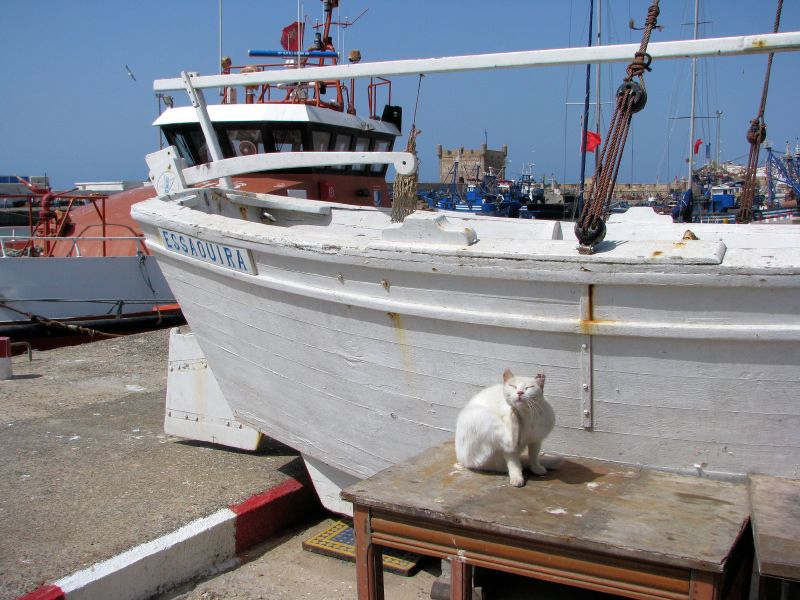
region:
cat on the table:
[444, 378, 542, 495]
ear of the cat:
[491, 366, 519, 377]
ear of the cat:
[532, 376, 552, 388]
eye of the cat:
[499, 379, 521, 388]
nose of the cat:
[512, 386, 525, 399]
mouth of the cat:
[502, 395, 531, 407]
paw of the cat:
[504, 464, 526, 491]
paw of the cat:
[523, 462, 551, 478]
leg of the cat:
[453, 446, 497, 479]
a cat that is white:
[429, 367, 589, 488]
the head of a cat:
[493, 369, 554, 410]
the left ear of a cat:
[521, 369, 557, 391]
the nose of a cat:
[514, 390, 527, 406]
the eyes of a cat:
[507, 378, 536, 391]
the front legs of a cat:
[484, 408, 552, 481]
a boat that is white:
[118, 166, 796, 502]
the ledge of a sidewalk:
[61, 518, 294, 575]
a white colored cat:
[445, 362, 568, 485]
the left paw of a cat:
[475, 442, 527, 494]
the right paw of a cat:
[521, 442, 553, 480]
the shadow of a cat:
[560, 438, 614, 506]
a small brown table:
[347, 454, 671, 598]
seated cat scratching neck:
[452, 369, 553, 486]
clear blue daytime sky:
[3, 1, 796, 188]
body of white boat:
[132, 192, 796, 552]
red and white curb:
[30, 481, 315, 598]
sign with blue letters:
[159, 227, 253, 279]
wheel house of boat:
[163, 100, 403, 199]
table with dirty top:
[344, 440, 746, 596]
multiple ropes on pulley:
[573, 2, 664, 250]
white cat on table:
[442, 357, 567, 487]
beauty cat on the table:
[476, 389, 554, 462]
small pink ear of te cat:
[496, 363, 517, 384]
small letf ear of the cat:
[533, 373, 545, 391]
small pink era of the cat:
[534, 377, 548, 387]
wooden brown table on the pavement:
[364, 489, 506, 555]